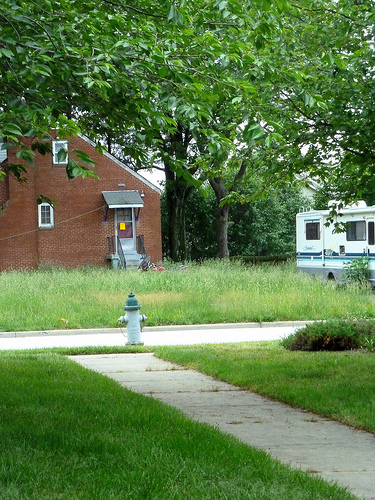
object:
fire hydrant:
[118, 290, 150, 343]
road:
[0, 319, 328, 353]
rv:
[294, 196, 375, 286]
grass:
[4, 263, 351, 325]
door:
[114, 203, 137, 267]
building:
[0, 110, 164, 269]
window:
[40, 205, 52, 225]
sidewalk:
[69, 347, 373, 499]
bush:
[281, 315, 362, 352]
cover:
[103, 190, 143, 217]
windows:
[42, 206, 52, 225]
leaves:
[72, 162, 84, 179]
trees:
[185, 2, 259, 259]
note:
[119, 220, 128, 232]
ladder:
[297, 203, 308, 217]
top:
[124, 292, 141, 310]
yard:
[5, 319, 374, 499]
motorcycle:
[135, 259, 184, 269]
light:
[139, 190, 146, 199]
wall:
[73, 184, 97, 260]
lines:
[298, 250, 374, 264]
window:
[306, 222, 319, 240]